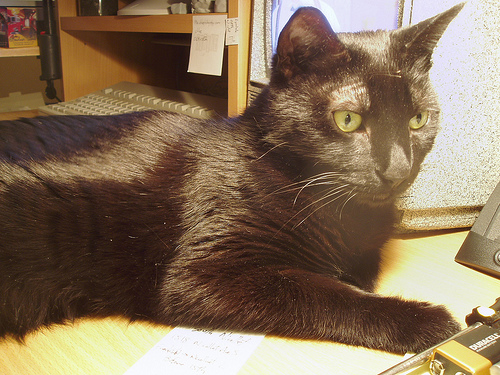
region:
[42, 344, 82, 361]
this is a table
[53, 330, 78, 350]
the table is wooden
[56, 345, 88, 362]
the table is brown in color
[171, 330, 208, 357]
this is a paper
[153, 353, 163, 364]
the paper is white in color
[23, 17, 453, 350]
this is a cat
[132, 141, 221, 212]
the fur is black in color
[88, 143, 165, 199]
the fur is shiny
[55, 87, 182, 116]
this is a keyboard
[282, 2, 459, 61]
these are the ears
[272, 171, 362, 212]
long whiskers on cat's face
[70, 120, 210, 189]
light reflecting on the cat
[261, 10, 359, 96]
black ears on cat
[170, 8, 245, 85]
white paper taped to desk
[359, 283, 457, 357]
cat's paw on table top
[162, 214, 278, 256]
shiny cat's fur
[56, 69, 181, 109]
tan keys on computer key board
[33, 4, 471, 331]
large cat laying on surface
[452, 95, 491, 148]
tiny black spots on the wall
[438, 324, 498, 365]
gold and black color on battery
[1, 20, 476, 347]
a black cat laying on a desk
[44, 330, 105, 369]
tan wood surface of the desk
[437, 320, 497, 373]
a battery sitting on the desk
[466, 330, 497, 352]
white lettering on the battery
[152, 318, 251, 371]
a piece of paper on the desk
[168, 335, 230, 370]
black lettering on the white paper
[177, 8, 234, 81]
a white post-it note stuck to a shelf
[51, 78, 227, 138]
a white computer keyboard on the desk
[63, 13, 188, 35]
tan wood surface of the shelf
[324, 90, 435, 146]
the cat's yellow eyes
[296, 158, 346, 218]
part of a whisker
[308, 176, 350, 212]
part of a whisker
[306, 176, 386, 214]
part of a whidkler